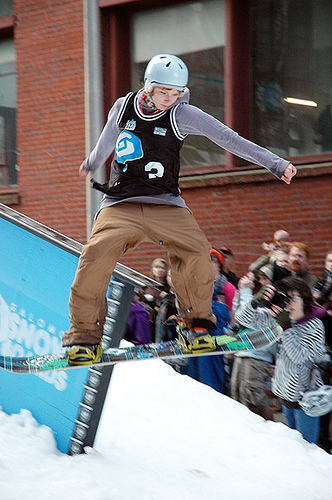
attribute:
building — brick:
[0, 1, 329, 301]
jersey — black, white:
[109, 106, 193, 204]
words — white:
[0, 297, 69, 389]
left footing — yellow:
[66, 342, 103, 366]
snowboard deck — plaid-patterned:
[1, 317, 283, 371]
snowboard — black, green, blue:
[1, 321, 291, 377]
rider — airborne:
[60, 46, 298, 368]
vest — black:
[155, 114, 183, 184]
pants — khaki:
[50, 192, 217, 345]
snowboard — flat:
[3, 314, 288, 376]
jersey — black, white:
[95, 90, 194, 200]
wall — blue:
[1, 215, 119, 456]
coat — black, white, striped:
[238, 286, 328, 404]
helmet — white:
[141, 50, 191, 91]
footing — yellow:
[177, 321, 216, 353]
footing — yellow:
[66, 342, 102, 365]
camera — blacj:
[262, 282, 294, 315]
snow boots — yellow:
[59, 323, 227, 354]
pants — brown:
[61, 201, 218, 344]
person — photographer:
[229, 275, 326, 442]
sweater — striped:
[233, 301, 328, 402]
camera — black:
[252, 269, 303, 317]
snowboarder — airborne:
[60, 51, 299, 367]